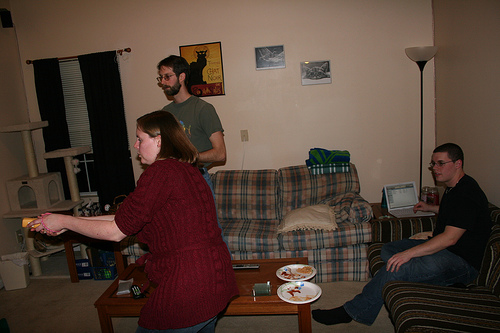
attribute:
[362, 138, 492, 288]
man — sitting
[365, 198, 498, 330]
couch — plaid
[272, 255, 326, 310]
plate — white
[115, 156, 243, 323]
sweater — red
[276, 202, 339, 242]
pillow — tan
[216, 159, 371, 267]
sofa — plaid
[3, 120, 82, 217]
cat house — empty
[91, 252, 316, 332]
table — wood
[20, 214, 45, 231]
controller — yellow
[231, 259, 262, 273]
remote control — black, silver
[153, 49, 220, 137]
man — standing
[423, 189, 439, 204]
containers — glass